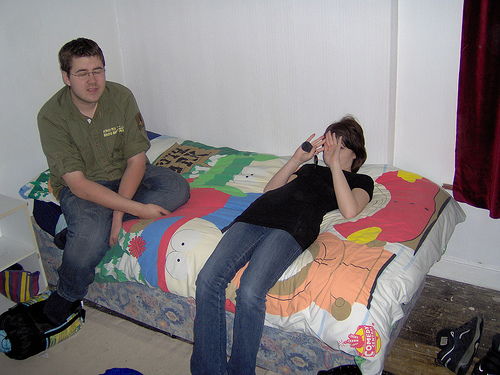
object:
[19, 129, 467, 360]
comforter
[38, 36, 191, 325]
man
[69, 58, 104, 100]
face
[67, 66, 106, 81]
glasses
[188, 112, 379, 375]
woman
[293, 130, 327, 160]
hand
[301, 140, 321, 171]
sunglasses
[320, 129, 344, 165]
hands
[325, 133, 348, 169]
face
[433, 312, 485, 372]
shoes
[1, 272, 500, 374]
floor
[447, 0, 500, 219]
curtain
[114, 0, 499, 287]
wall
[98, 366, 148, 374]
shirt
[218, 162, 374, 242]
shirt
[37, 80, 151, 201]
shirt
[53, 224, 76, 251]
sock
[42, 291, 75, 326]
sock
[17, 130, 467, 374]
bed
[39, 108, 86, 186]
sleeves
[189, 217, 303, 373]
jeans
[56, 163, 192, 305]
jeans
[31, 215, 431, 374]
box spring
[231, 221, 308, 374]
legs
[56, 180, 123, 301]
legs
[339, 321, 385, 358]
logo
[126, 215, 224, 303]
cartoon character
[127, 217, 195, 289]
hat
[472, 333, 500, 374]
shoe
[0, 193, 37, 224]
shelf